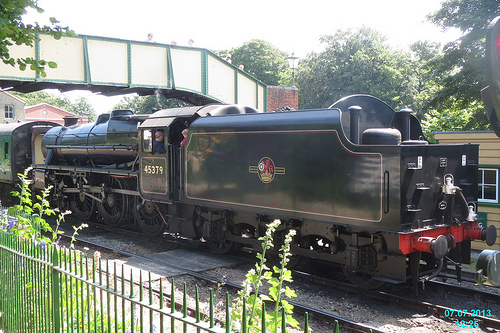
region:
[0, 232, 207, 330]
a green metal gate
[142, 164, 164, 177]
the number 45379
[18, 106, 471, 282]
a big black train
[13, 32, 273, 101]
a white and green footbridge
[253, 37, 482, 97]
leafy trees in the background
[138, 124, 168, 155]
the train driver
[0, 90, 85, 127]
two house in the distance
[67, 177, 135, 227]
two big wheels of the train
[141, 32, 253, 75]
several people watching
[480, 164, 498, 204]
a white and green window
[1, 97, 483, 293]
black and green train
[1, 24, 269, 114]
white and green bridge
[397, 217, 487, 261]
red bracket on train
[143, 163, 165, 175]
white numbers on train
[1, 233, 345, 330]
green iron picket fence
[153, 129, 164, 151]
man sitting in train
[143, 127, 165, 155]
window in train car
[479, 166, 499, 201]
white window on building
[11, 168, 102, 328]
green plants by fence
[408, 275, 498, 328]
metal and brown tracks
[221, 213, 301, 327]
weeds growing by the fence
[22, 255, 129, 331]
green metal fence beside the train tracks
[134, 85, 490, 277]
black engine on the train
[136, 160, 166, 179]
numbers on the side of the train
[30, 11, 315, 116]
bridge over the train tracks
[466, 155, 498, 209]
window in building behind train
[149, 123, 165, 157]
person in the window of the train engine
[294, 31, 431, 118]
trees behind the train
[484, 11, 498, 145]
light for the train tracks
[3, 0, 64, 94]
tree limb hanging over the fence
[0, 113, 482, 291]
Train on the tracks.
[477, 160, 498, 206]
Green window trim on window.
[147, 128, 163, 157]
Person on the train.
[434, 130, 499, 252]
Tan siding on the building.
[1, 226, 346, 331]
Green fence in the forefront.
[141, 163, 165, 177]
Numbers on the side of the train.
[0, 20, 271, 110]
Bridge over the train.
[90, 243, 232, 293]
Wood walk way on the tracks.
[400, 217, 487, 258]
Red paint on front of the train.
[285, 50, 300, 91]
Light on the building.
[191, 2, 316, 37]
Clear cloudless white sky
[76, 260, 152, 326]
Short green metal fence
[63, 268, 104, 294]
Long horizontal metal rod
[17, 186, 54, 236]
Green leafy sprouting leaves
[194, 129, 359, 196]
Jungle green train wagon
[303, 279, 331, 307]
Small grey stone pebbles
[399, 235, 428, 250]
Patch of red metal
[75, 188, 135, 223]
Big strong train wheels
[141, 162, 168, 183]
Individual train identification number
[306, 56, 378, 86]
Thick green bushy trees